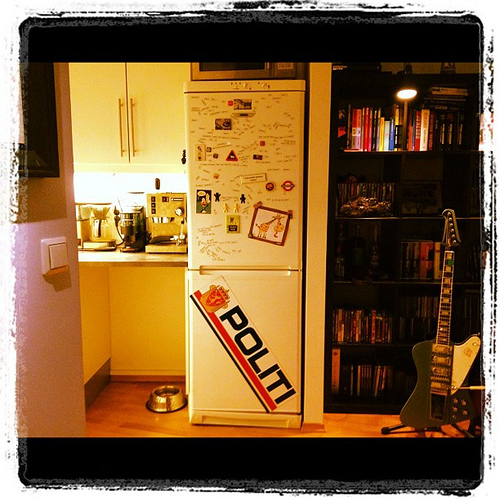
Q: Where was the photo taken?
A: It was taken at the kitchen.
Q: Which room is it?
A: It is a kitchen.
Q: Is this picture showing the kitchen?
A: Yes, it is showing the kitchen.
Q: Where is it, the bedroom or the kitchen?
A: It is the kitchen.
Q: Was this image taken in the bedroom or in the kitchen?
A: It was taken at the kitchen.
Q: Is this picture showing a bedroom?
A: No, the picture is showing a kitchen.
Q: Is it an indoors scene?
A: Yes, it is indoors.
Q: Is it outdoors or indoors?
A: It is indoors.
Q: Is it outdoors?
A: No, it is indoors.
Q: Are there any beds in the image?
A: No, there are no beds.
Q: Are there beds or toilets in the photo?
A: No, there are no beds or toilets.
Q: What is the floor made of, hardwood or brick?
A: The floor is made of hardwood.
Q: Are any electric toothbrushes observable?
A: No, there are no electric toothbrushes.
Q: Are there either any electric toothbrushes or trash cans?
A: No, there are no electric toothbrushes or trash cans.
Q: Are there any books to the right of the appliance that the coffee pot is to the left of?
A: Yes, there are books to the right of the refrigerator.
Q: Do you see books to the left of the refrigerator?
A: No, the books are to the right of the refrigerator.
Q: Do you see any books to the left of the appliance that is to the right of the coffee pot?
A: No, the books are to the right of the refrigerator.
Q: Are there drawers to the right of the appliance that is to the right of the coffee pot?
A: No, there are books to the right of the refrigerator.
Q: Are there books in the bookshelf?
A: Yes, there are books in the bookshelf.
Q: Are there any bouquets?
A: No, there are no bouquets.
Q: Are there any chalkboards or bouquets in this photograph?
A: No, there are no bouquets or chalkboards.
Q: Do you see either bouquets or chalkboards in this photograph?
A: No, there are no bouquets or chalkboards.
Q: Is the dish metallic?
A: Yes, the dish is metallic.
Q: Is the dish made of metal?
A: Yes, the dish is made of metal.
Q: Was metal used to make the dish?
A: Yes, the dish is made of metal.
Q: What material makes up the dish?
A: The dish is made of metal.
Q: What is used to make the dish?
A: The dish is made of metal.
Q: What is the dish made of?
A: The dish is made of metal.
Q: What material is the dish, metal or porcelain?
A: The dish is made of metal.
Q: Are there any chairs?
A: No, there are no chairs.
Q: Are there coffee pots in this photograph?
A: Yes, there is a coffee pot.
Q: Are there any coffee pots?
A: Yes, there is a coffee pot.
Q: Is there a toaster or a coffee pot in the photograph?
A: Yes, there is a coffee pot.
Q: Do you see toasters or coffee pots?
A: Yes, there is a coffee pot.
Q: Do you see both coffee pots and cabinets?
A: Yes, there are both a coffee pot and a cabinet.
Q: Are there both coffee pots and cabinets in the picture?
A: Yes, there are both a coffee pot and a cabinet.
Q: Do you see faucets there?
A: No, there are no faucets.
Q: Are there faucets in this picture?
A: No, there are no faucets.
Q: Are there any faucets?
A: No, there are no faucets.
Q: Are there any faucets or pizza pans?
A: No, there are no faucets or pizza pans.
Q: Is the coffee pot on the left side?
A: Yes, the coffee pot is on the left of the image.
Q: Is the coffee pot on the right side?
A: No, the coffee pot is on the left of the image.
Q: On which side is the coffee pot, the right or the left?
A: The coffee pot is on the left of the image.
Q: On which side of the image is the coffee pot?
A: The coffee pot is on the left of the image.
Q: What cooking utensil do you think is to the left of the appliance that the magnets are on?
A: The cooking utensil is a coffee pot.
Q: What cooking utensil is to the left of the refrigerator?
A: The cooking utensil is a coffee pot.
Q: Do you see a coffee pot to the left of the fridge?
A: Yes, there is a coffee pot to the left of the fridge.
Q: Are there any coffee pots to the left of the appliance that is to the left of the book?
A: Yes, there is a coffee pot to the left of the fridge.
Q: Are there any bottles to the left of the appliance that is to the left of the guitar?
A: No, there is a coffee pot to the left of the freezer.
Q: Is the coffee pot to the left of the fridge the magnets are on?
A: Yes, the coffee pot is to the left of the fridge.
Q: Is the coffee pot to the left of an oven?
A: No, the coffee pot is to the left of the fridge.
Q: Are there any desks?
A: No, there are no desks.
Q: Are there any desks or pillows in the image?
A: No, there are no desks or pillows.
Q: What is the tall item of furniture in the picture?
A: The piece of furniture is a bookshelf.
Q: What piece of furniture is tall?
A: The piece of furniture is a bookshelf.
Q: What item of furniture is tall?
A: The piece of furniture is a bookshelf.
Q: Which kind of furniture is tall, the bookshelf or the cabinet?
A: The bookshelf is tall.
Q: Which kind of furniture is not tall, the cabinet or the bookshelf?
A: The cabinet is not tall.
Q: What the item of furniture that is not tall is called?
A: The piece of furniture is a cabinet.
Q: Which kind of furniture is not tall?
A: The furniture is a cabinet.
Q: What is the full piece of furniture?
A: The piece of furniture is a bookshelf.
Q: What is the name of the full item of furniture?
A: The piece of furniture is a bookshelf.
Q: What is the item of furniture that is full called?
A: The piece of furniture is a bookshelf.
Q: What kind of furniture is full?
A: The furniture is a bookshelf.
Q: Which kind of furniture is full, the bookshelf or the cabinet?
A: The bookshelf is full.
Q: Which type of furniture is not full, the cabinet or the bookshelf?
A: The cabinet is not full.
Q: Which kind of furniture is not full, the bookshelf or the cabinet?
A: The cabinet is not full.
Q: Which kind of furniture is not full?
A: The furniture is a cabinet.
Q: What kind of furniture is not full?
A: The furniture is a cabinet.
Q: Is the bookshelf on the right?
A: Yes, the bookshelf is on the right of the image.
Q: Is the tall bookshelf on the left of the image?
A: No, the bookshelf is on the right of the image.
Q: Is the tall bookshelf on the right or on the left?
A: The bookshelf is on the right of the image.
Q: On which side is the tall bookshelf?
A: The bookshelf is on the right of the image.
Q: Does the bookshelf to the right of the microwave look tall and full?
A: Yes, the bookshelf is tall and full.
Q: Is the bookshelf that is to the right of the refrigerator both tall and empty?
A: No, the bookshelf is tall but full.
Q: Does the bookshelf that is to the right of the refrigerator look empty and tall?
A: No, the bookshelf is tall but full.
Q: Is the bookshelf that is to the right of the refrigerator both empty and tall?
A: No, the bookshelf is tall but full.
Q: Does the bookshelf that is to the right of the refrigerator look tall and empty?
A: No, the bookshelf is tall but full.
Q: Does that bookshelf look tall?
A: Yes, the bookshelf is tall.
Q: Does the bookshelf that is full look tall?
A: Yes, the bookshelf is tall.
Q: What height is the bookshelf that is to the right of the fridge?
A: The bookshelf is tall.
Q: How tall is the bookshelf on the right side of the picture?
A: The bookshelf is tall.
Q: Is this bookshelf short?
A: No, the bookshelf is tall.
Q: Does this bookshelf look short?
A: No, the bookshelf is tall.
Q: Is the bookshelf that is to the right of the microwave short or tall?
A: The bookshelf is tall.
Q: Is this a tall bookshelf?
A: Yes, this is a tall bookshelf.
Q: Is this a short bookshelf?
A: No, this is a tall bookshelf.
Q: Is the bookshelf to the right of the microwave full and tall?
A: Yes, the bookshelf is full and tall.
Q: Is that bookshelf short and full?
A: No, the bookshelf is full but tall.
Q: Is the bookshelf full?
A: Yes, the bookshelf is full.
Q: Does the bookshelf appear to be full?
A: Yes, the bookshelf is full.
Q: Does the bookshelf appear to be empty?
A: No, the bookshelf is full.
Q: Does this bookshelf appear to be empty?
A: No, the bookshelf is full.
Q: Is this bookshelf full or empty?
A: The bookshelf is full.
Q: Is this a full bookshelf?
A: Yes, this is a full bookshelf.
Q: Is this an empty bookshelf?
A: No, this is a full bookshelf.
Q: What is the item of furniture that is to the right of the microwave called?
A: The piece of furniture is a bookshelf.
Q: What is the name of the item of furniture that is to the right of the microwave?
A: The piece of furniture is a bookshelf.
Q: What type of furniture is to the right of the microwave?
A: The piece of furniture is a bookshelf.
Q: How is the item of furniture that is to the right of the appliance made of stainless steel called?
A: The piece of furniture is a bookshelf.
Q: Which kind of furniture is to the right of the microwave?
A: The piece of furniture is a bookshelf.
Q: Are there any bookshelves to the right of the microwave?
A: Yes, there is a bookshelf to the right of the microwave.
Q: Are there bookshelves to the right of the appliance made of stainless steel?
A: Yes, there is a bookshelf to the right of the microwave.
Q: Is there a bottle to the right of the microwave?
A: No, there is a bookshelf to the right of the microwave.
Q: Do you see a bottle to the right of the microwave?
A: No, there is a bookshelf to the right of the microwave.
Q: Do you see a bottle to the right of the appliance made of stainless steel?
A: No, there is a bookshelf to the right of the microwave.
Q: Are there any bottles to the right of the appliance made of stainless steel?
A: No, there is a bookshelf to the right of the microwave.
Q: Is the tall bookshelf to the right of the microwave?
A: Yes, the bookshelf is to the right of the microwave.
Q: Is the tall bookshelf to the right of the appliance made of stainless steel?
A: Yes, the bookshelf is to the right of the microwave.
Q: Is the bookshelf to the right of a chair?
A: No, the bookshelf is to the right of the microwave.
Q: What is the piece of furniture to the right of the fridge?
A: The piece of furniture is a bookshelf.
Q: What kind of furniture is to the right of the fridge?
A: The piece of furniture is a bookshelf.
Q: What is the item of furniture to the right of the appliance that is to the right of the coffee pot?
A: The piece of furniture is a bookshelf.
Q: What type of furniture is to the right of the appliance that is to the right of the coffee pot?
A: The piece of furniture is a bookshelf.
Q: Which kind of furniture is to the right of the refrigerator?
A: The piece of furniture is a bookshelf.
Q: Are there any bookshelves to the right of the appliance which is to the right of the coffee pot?
A: Yes, there is a bookshelf to the right of the freezer.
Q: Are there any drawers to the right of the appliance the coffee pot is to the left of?
A: No, there is a bookshelf to the right of the freezer.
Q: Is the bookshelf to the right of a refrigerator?
A: Yes, the bookshelf is to the right of a refrigerator.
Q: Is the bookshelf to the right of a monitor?
A: No, the bookshelf is to the right of a refrigerator.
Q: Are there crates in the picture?
A: No, there are no crates.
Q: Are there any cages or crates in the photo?
A: No, there are no crates or cages.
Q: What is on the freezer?
A: The magnets are on the freezer.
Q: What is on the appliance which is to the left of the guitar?
A: The magnets are on the freezer.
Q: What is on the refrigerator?
A: The magnets are on the freezer.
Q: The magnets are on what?
A: The magnets are on the fridge.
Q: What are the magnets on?
A: The magnets are on the fridge.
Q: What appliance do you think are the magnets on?
A: The magnets are on the fridge.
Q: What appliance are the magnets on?
A: The magnets are on the fridge.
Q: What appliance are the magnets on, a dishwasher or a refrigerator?
A: The magnets are on a refrigerator.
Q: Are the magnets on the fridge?
A: Yes, the magnets are on the fridge.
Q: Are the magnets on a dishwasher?
A: No, the magnets are on the fridge.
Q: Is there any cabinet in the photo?
A: Yes, there is a cabinet.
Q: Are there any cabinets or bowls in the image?
A: Yes, there is a cabinet.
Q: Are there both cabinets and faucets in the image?
A: No, there is a cabinet but no faucets.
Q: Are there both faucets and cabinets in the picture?
A: No, there is a cabinet but no faucets.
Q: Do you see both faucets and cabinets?
A: No, there is a cabinet but no faucets.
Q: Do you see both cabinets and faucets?
A: No, there is a cabinet but no faucets.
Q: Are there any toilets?
A: No, there are no toilets.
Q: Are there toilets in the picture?
A: No, there are no toilets.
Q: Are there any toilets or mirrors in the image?
A: No, there are no toilets or mirrors.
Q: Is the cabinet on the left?
A: Yes, the cabinet is on the left of the image.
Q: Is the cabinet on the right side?
A: No, the cabinet is on the left of the image.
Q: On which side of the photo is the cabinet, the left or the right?
A: The cabinet is on the left of the image.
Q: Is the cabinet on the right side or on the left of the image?
A: The cabinet is on the left of the image.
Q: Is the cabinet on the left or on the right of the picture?
A: The cabinet is on the left of the image.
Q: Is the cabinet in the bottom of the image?
A: No, the cabinet is in the top of the image.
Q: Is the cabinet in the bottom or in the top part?
A: The cabinet is in the top of the image.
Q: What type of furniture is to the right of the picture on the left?
A: The piece of furniture is a cabinet.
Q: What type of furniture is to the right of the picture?
A: The piece of furniture is a cabinet.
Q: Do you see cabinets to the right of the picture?
A: Yes, there is a cabinet to the right of the picture.